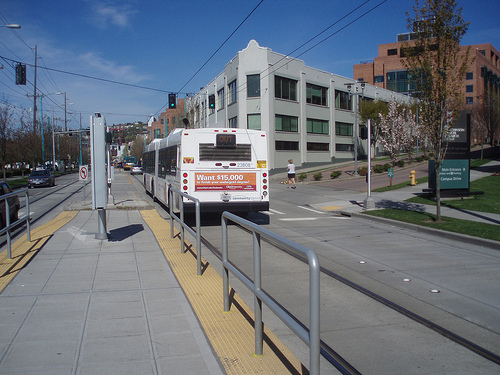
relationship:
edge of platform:
[136, 205, 308, 373] [1, 207, 306, 372]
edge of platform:
[0, 207, 81, 294] [1, 207, 306, 372]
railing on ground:
[218, 210, 321, 375] [5, 169, 304, 374]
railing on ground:
[169, 186, 202, 277] [5, 169, 304, 374]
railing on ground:
[0, 186, 33, 263] [5, 169, 304, 374]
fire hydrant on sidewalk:
[407, 166, 419, 185] [365, 153, 499, 200]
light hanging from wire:
[209, 102, 216, 108] [42, 60, 216, 99]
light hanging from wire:
[170, 101, 175, 108] [42, 60, 216, 99]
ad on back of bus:
[197, 172, 258, 194] [141, 127, 266, 216]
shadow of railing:
[5, 232, 52, 277] [1, 191, 32, 258]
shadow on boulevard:
[5, 232, 52, 277] [0, 159, 498, 375]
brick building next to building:
[353, 23, 500, 162] [184, 39, 445, 171]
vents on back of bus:
[198, 143, 254, 165] [175, 121, 270, 216]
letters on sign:
[439, 165, 467, 183] [423, 137, 473, 194]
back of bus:
[184, 125, 274, 206] [118, 121, 288, 238]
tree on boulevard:
[387, 15, 470, 215] [0, 159, 498, 375]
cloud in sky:
[85, 3, 136, 33] [103, 47, 159, 74]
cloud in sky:
[0, 0, 500, 123] [103, 47, 159, 74]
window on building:
[244, 73, 259, 96] [187, 45, 371, 127]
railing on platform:
[195, 201, 413, 371] [1, 207, 306, 372]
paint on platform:
[167, 253, 274, 348] [1, 207, 306, 372]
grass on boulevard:
[371, 167, 499, 254] [200, 134, 497, 372]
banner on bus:
[194, 171, 261, 195] [131, 120, 272, 222]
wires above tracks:
[6, 30, 178, 113] [204, 221, 495, 373]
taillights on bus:
[260, 172, 268, 199] [141, 127, 266, 216]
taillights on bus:
[178, 169, 195, 201] [141, 127, 266, 216]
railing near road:
[218, 210, 321, 375] [0, 171, 498, 373]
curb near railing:
[122, 209, 314, 374] [221, 211, 318, 373]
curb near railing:
[122, 209, 314, 374] [169, 186, 201, 273]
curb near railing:
[122, 209, 314, 374] [3, 185, 32, 260]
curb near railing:
[1, 210, 77, 293] [221, 211, 318, 373]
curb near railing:
[1, 210, 77, 293] [169, 186, 201, 273]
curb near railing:
[1, 210, 77, 293] [3, 185, 32, 260]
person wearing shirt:
[278, 156, 303, 190] [283, 157, 305, 189]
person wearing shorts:
[287, 159, 296, 190] [287, 171, 294, 178]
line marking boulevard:
[278, 215, 355, 223] [0, 159, 498, 375]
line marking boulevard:
[296, 202, 323, 214] [0, 159, 498, 375]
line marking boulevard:
[269, 206, 285, 216] [0, 159, 498, 375]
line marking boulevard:
[258, 210, 274, 217] [0, 159, 498, 375]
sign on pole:
[79, 164, 88, 181] [79, 181, 89, 206]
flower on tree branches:
[374, 105, 421, 152] [362, 95, 425, 165]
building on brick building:
[54, 36, 442, 171] [353, 23, 500, 162]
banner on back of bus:
[194, 171, 258, 192] [101, 109, 284, 248]